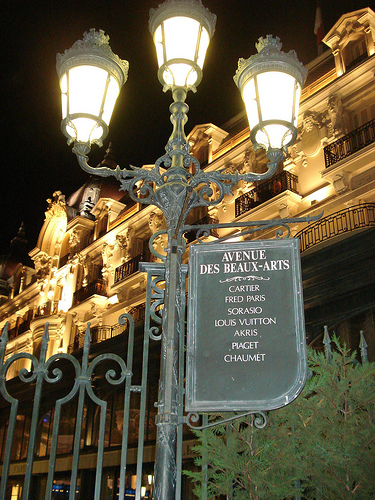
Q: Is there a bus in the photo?
A: No, there are no buses.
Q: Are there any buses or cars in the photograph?
A: No, there are no buses or cars.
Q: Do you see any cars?
A: No, there are no cars.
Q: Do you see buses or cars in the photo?
A: No, there are no cars or buses.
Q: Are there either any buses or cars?
A: No, there are no cars or buses.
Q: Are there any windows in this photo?
A: Yes, there are windows.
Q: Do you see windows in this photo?
A: Yes, there are windows.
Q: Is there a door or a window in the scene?
A: Yes, there are windows.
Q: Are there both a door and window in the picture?
A: No, there are windows but no doors.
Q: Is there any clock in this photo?
A: No, there are no clocks.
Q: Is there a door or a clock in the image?
A: No, there are no clocks or doors.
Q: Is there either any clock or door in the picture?
A: No, there are no clocks or doors.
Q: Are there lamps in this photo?
A: Yes, there is a lamp.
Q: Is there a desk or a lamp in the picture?
A: Yes, there is a lamp.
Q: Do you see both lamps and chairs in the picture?
A: No, there is a lamp but no chairs.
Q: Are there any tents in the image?
A: No, there are no tents.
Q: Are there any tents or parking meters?
A: No, there are no tents or parking meters.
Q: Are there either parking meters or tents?
A: No, there are no tents or parking meters.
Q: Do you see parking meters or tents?
A: No, there are no tents or parking meters.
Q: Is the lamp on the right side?
A: Yes, the lamp is on the right of the image.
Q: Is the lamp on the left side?
A: No, the lamp is on the right of the image.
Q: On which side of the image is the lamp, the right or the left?
A: The lamp is on the right of the image.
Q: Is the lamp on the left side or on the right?
A: The lamp is on the right of the image.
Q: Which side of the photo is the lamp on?
A: The lamp is on the right of the image.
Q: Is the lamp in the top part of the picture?
A: Yes, the lamp is in the top of the image.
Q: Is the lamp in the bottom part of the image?
A: No, the lamp is in the top of the image.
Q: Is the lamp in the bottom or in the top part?
A: The lamp is in the top of the image.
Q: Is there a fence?
A: Yes, there is a fence.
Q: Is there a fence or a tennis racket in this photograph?
A: Yes, there is a fence.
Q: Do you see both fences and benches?
A: No, there is a fence but no benches.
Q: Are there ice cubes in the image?
A: No, there are no ice cubes.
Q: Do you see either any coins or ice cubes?
A: No, there are no ice cubes or coins.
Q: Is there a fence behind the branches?
A: Yes, there is a fence behind the branches.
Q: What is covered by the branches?
A: The fence is covered by the branches.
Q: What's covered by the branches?
A: The fence is covered by the branches.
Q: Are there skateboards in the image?
A: No, there are no skateboards.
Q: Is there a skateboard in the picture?
A: No, there are no skateboards.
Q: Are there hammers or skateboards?
A: No, there are no skateboards or hammers.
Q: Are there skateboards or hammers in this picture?
A: No, there are no skateboards or hammers.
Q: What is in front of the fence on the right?
A: The branches are in front of the fence.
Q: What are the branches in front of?
A: The branches are in front of the fence.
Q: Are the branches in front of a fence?
A: Yes, the branches are in front of a fence.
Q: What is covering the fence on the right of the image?
A: The branches are covering the fence.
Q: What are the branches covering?
A: The branches are covering the fence.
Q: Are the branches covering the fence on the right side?
A: Yes, the branches are covering the fence.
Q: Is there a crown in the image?
A: Yes, there is a crown.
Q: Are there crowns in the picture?
A: Yes, there is a crown.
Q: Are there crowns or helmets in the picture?
A: Yes, there is a crown.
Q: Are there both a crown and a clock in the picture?
A: No, there is a crown but no clocks.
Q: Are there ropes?
A: No, there are no ropes.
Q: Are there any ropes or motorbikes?
A: No, there are no ropes or motorbikes.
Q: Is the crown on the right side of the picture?
A: Yes, the crown is on the right of the image.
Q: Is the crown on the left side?
A: No, the crown is on the right of the image.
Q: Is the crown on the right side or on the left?
A: The crown is on the right of the image.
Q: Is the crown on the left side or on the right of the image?
A: The crown is on the right of the image.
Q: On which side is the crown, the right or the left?
A: The crown is on the right of the image.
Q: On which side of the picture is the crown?
A: The crown is on the right of the image.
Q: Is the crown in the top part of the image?
A: Yes, the crown is in the top of the image.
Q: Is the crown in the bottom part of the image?
A: No, the crown is in the top of the image.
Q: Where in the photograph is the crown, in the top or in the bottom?
A: The crown is in the top of the image.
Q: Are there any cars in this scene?
A: No, there are no cars.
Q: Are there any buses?
A: No, there are no buses.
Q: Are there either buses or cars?
A: No, there are no buses or cars.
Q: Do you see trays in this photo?
A: No, there are no trays.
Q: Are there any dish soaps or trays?
A: No, there are no trays or dish soaps.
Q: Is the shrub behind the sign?
A: Yes, the shrub is behind the sign.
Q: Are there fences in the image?
A: Yes, there is a fence.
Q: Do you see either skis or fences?
A: Yes, there is a fence.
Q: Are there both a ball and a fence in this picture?
A: No, there is a fence but no balls.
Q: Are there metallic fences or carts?
A: Yes, there is a metal fence.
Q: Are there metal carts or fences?
A: Yes, there is a metal fence.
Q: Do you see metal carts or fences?
A: Yes, there is a metal fence.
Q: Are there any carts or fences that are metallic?
A: Yes, the fence is metallic.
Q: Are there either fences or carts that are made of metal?
A: Yes, the fence is made of metal.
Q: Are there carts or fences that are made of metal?
A: Yes, the fence is made of metal.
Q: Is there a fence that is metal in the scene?
A: Yes, there is a metal fence.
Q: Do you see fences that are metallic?
A: Yes, there is a fence that is metallic.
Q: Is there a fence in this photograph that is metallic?
A: Yes, there is a fence that is metallic.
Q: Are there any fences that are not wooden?
A: Yes, there is a metallic fence.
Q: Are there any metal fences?
A: Yes, there is a fence that is made of metal.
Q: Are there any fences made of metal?
A: Yes, there is a fence that is made of metal.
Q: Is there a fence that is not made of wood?
A: Yes, there is a fence that is made of metal.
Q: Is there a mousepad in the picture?
A: No, there are no mouse pads.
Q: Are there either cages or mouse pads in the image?
A: No, there are no mouse pads or cages.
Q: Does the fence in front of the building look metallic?
A: Yes, the fence is metallic.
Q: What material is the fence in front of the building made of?
A: The fence is made of metal.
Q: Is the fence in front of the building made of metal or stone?
A: The fence is made of metal.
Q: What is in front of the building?
A: The fence is in front of the building.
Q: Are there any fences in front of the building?
A: Yes, there is a fence in front of the building.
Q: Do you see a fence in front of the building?
A: Yes, there is a fence in front of the building.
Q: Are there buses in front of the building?
A: No, there is a fence in front of the building.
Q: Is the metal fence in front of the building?
A: Yes, the fence is in front of the building.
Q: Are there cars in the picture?
A: No, there are no cars.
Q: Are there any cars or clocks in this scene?
A: No, there are no cars or clocks.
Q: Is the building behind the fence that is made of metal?
A: Yes, the building is behind the fence.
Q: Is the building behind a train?
A: No, the building is behind the fence.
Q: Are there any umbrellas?
A: No, there are no umbrellas.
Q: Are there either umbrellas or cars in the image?
A: No, there are no umbrellas or cars.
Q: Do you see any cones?
A: No, there are no cones.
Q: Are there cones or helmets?
A: No, there are no cones or helmets.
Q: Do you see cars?
A: No, there are no cars.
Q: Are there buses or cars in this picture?
A: No, there are no cars or buses.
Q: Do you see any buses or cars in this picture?
A: No, there are no cars or buses.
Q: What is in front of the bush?
A: The sign is in front of the bush.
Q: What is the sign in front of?
A: The sign is in front of the shrub.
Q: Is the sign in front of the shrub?
A: Yes, the sign is in front of the shrub.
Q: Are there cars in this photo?
A: No, there are no cars.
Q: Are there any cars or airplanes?
A: No, there are no cars or airplanes.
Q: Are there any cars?
A: No, there are no cars.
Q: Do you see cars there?
A: No, there are no cars.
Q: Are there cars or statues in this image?
A: No, there are no cars or statues.